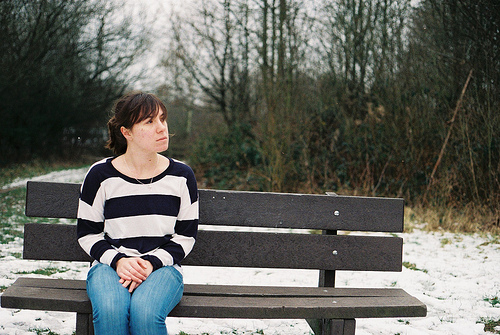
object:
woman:
[75, 90, 198, 335]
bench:
[0, 181, 427, 335]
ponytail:
[104, 115, 128, 154]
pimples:
[137, 127, 151, 141]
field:
[1, 216, 500, 335]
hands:
[116, 256, 153, 293]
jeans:
[85, 262, 183, 335]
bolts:
[334, 210, 340, 215]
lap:
[125, 296, 135, 319]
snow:
[443, 284, 450, 287]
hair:
[104, 90, 167, 155]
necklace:
[123, 153, 159, 190]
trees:
[175, 0, 500, 192]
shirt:
[74, 154, 200, 272]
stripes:
[102, 214, 177, 239]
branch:
[256, 0, 311, 77]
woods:
[0, 0, 500, 209]